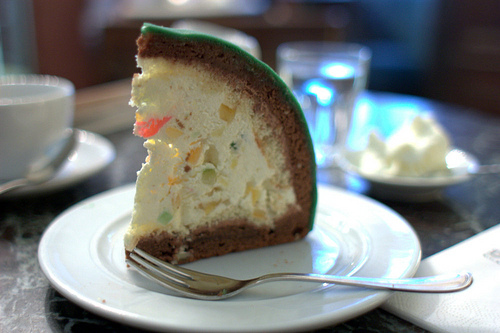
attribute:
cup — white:
[0, 69, 87, 185]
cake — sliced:
[123, 25, 336, 263]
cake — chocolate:
[139, 29, 319, 256]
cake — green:
[93, 26, 331, 260]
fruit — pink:
[126, 114, 173, 144]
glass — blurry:
[280, 33, 373, 167]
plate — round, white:
[38, 177, 420, 331]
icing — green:
[140, 16, 331, 232]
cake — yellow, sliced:
[123, 18, 318, 273]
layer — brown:
[123, 209, 309, 263]